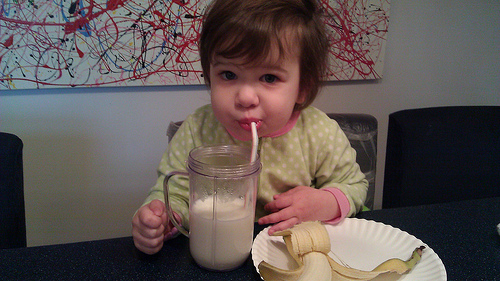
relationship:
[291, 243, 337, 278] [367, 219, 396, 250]
banana on plate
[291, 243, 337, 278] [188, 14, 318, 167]
banana near girl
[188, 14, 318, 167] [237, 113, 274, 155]
girl sucking straw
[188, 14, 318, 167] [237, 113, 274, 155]
girl with straw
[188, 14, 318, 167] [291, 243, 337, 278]
girl near banana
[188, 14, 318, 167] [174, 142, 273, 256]
girl near glass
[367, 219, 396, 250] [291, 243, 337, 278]
plate holding banana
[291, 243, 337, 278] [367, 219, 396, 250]
banana next to plate